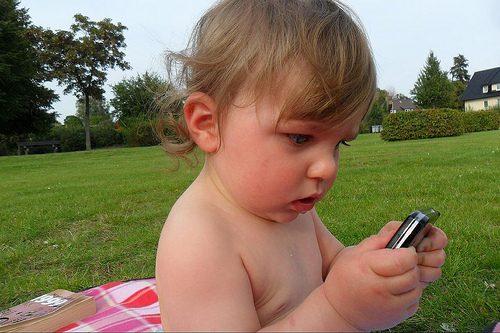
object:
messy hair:
[142, 0, 377, 173]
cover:
[0, 289, 84, 324]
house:
[461, 66, 500, 113]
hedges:
[379, 106, 499, 142]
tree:
[0, 0, 63, 156]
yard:
[0, 80, 497, 314]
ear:
[182, 90, 221, 152]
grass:
[5, 130, 499, 331]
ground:
[0, 128, 500, 330]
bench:
[16, 138, 61, 155]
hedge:
[1, 114, 178, 156]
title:
[30, 292, 68, 309]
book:
[0, 288, 99, 332]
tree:
[39, 13, 134, 150]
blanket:
[53, 277, 164, 332]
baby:
[132, 0, 448, 332]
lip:
[290, 192, 318, 212]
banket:
[9, 215, 143, 269]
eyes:
[277, 131, 314, 146]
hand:
[320, 230, 422, 331]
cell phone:
[382, 206, 440, 250]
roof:
[460, 67, 499, 101]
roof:
[397, 99, 416, 109]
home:
[387, 93, 421, 113]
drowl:
[295, 201, 314, 214]